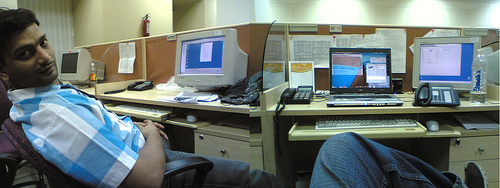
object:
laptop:
[326, 47, 405, 106]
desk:
[261, 89, 498, 187]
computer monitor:
[171, 25, 248, 89]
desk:
[96, 81, 265, 173]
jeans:
[308, 131, 467, 187]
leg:
[305, 131, 467, 187]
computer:
[409, 36, 485, 98]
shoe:
[460, 161, 491, 188]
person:
[1, 8, 287, 182]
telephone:
[275, 85, 314, 105]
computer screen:
[415, 42, 477, 84]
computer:
[164, 27, 254, 107]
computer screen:
[181, 35, 223, 74]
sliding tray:
[287, 125, 459, 142]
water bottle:
[466, 50, 494, 106]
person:
[0, 6, 289, 188]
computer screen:
[55, 52, 80, 73]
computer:
[56, 49, 109, 92]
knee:
[320, 130, 364, 148]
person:
[307, 130, 489, 187]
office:
[0, 0, 500, 187]